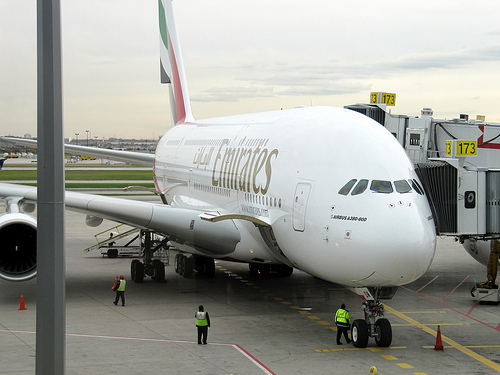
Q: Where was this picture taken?
A: At an airport.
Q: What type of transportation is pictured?
A: An airplane.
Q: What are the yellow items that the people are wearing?
A: Vests.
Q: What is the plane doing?
A: It is parked.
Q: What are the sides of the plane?
A: Wings.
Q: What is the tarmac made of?
A: Concrete.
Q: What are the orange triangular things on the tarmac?
A: Cones.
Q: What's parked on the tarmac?
A: Airplane.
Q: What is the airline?
A: Emirates.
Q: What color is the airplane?
A: White.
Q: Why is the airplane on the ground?
A: It is at the airport.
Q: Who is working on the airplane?
A: Employees of the airport.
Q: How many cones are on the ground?
A: Two.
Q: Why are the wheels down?
A: It's landed.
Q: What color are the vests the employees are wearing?
A: Green.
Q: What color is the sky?
A: Gray.